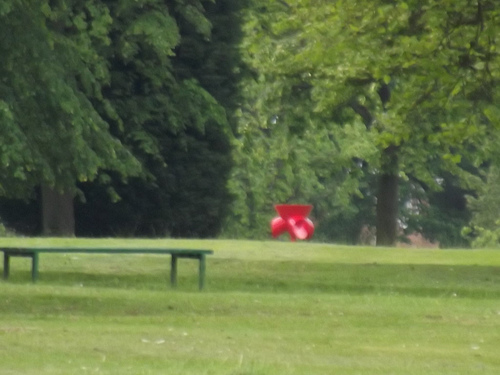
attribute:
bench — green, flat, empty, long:
[2, 248, 213, 289]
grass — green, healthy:
[2, 237, 500, 374]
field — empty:
[0, 2, 499, 373]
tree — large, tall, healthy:
[0, 2, 223, 238]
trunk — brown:
[39, 159, 77, 238]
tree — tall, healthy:
[281, 6, 466, 245]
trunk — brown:
[376, 151, 399, 248]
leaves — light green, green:
[329, 17, 454, 149]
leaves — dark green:
[19, 37, 163, 135]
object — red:
[271, 204, 314, 242]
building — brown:
[402, 223, 441, 247]